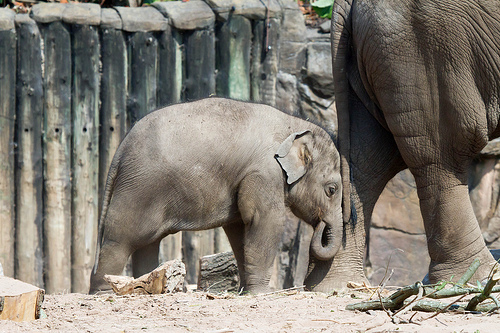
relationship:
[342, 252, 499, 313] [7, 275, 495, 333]
branches on ground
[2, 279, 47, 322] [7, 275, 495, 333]
wood on ground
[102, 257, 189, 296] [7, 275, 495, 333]
wood on ground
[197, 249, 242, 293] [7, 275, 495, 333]
wood on ground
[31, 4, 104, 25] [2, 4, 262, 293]
rock on fence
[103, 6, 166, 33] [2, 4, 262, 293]
rock on fence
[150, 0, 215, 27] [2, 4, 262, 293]
rock on fence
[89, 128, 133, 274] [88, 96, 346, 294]
tail of elephant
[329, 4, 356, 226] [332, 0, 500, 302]
tail of elephant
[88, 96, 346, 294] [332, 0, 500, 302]
elephant beside elephant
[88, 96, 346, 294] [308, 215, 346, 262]
elephant with trunk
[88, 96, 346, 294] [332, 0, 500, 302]
elephant with mother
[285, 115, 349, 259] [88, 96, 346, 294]
head of elephant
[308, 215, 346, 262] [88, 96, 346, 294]
trunk of elephant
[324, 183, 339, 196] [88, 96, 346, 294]
eye of elephant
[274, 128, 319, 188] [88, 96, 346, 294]
ear of elephant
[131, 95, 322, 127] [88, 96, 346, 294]
back of elephant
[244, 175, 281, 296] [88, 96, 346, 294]
leg of elephant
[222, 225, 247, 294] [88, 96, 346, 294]
leg of elephant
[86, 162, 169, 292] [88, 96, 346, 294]
leg of elephant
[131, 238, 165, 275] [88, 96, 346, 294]
leg of elephant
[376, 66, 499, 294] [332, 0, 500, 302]
leg of elephant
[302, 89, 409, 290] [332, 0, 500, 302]
leg of elephant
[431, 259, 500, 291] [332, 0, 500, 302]
foot of elephant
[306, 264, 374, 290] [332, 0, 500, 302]
foot of elephant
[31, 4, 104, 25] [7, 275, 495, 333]
rock on ground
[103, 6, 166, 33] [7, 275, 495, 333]
rock on ground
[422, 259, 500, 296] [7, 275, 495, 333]
branch on ground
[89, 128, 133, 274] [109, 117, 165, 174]
tail on backside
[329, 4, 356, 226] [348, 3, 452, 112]
tail on backside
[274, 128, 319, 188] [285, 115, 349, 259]
ear on head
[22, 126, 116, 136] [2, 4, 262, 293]
holes in fence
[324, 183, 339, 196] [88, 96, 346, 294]
eye of calf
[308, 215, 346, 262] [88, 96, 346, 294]
trunk of calf